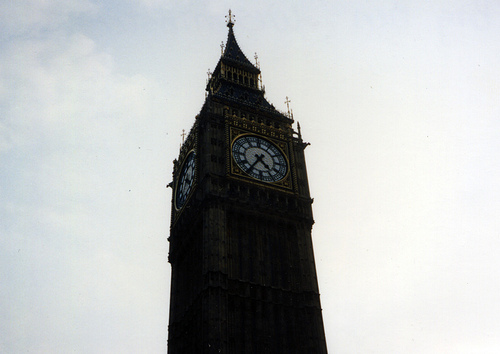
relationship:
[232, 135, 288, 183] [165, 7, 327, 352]
clock on clock tower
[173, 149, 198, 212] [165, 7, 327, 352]
clock on clock tower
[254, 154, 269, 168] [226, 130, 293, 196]
hand on clock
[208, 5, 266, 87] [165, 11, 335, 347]
spire on tower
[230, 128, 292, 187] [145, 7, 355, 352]
clock on tower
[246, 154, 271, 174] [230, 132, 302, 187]
hand on clock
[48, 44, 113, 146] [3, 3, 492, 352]
clouds in sky